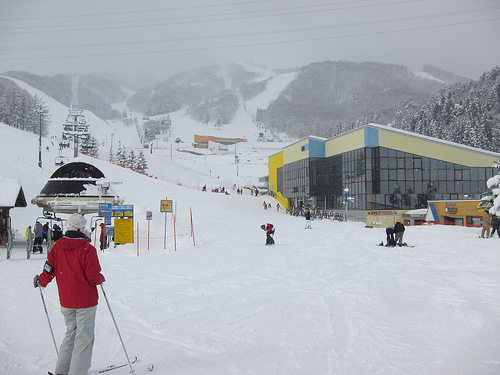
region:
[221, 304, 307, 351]
Part of the snow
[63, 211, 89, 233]
The head of the person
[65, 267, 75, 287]
Part of the red jacket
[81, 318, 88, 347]
Part of the pants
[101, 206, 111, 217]
Part of the sign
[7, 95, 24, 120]
A tree in distance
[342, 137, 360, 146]
Part of the building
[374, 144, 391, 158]
A window on the building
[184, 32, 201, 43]
Part of the power line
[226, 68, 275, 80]
A moutain in distance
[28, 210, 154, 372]
Skier holding two ski poles.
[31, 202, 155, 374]
Skier wearing a white beanie cap.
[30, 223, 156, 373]
Skier wearing a red jacket.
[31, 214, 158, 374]
Skier wearing white pants.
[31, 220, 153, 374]
Skier wearing an arm band on their left arm.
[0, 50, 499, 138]
Mountains covered in white snow.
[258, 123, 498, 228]
A ski lodge with multiple glass windows.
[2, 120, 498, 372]
White snow covering the ground.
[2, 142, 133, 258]
Skiers riding ski lift to the mountain's top.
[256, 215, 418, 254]
Three people preparing themselves for skiing.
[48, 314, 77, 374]
leg of a person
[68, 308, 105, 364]
leg of a person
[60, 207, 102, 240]
a head of a person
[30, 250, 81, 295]
arm of a person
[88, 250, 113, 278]
an arm of a person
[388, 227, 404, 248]
leg of a person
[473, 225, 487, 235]
leg of a person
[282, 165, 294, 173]
window of a building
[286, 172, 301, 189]
window of a building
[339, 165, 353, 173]
window of a building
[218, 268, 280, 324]
Part of the snow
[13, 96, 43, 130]
Part of the tree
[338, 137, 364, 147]
Part of the building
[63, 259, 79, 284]
Part of the red jacket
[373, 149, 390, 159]
A window on the building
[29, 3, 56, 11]
Part of the sky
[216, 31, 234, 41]
Part of the power line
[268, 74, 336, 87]
Part of the mountain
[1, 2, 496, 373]
winter scene at a large ski resort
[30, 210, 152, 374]
skier with tan pants and a red jacket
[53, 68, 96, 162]
ski chair lift up the mountain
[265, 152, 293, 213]
yellow portion of building with many windows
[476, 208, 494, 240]
person standing in the snow dressed in tan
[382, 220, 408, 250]
two skiers bent over and putting on their equipment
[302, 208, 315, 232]
skier with white pants and a black jacket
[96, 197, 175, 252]
blue and yellow signs near the start of the lift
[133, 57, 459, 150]
mountain with one large trail and more smaller trails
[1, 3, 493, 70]
dark gray cloudy sky over mountains